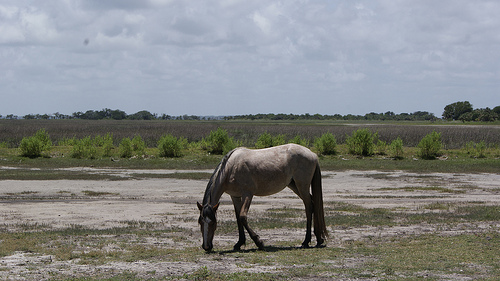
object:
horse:
[196, 142, 331, 254]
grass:
[0, 149, 500, 182]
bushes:
[387, 136, 408, 162]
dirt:
[103, 207, 172, 235]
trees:
[56, 111, 61, 119]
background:
[0, 0, 500, 150]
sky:
[0, 0, 500, 119]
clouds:
[166, 20, 182, 31]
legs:
[239, 187, 264, 250]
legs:
[288, 185, 313, 247]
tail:
[313, 163, 333, 244]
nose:
[202, 242, 210, 249]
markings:
[201, 216, 211, 248]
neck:
[202, 178, 224, 211]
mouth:
[200, 241, 216, 252]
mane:
[209, 149, 237, 206]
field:
[0, 121, 500, 281]